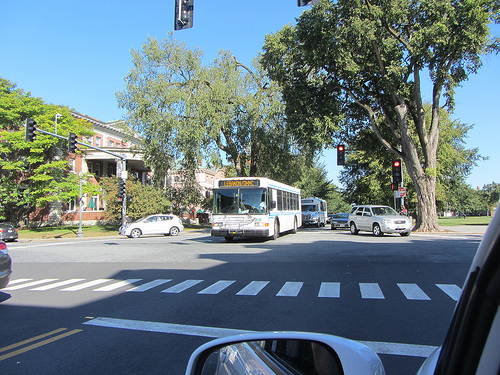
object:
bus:
[210, 176, 305, 242]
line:
[193, 279, 237, 296]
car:
[117, 212, 187, 239]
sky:
[0, 2, 500, 192]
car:
[182, 197, 500, 375]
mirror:
[192, 338, 346, 374]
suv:
[348, 199, 413, 237]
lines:
[433, 282, 466, 303]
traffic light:
[334, 145, 347, 153]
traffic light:
[393, 160, 403, 171]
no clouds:
[2, 0, 498, 199]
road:
[7, 224, 490, 374]